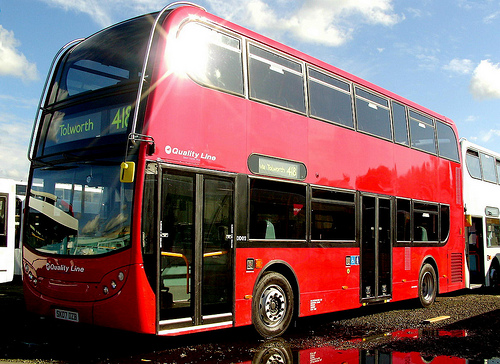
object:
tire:
[247, 270, 296, 339]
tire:
[408, 260, 438, 307]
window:
[353, 95, 395, 143]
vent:
[449, 252, 461, 283]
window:
[434, 120, 460, 164]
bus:
[19, 0, 466, 340]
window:
[248, 175, 304, 238]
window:
[304, 198, 356, 246]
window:
[390, 198, 415, 245]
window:
[174, 37, 245, 98]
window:
[404, 117, 442, 156]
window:
[41, 12, 162, 108]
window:
[244, 55, 308, 119]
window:
[304, 77, 355, 131]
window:
[387, 99, 410, 148]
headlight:
[30, 278, 39, 285]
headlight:
[116, 272, 126, 283]